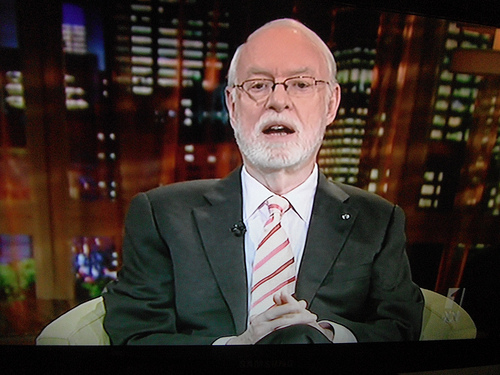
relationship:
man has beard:
[103, 17, 424, 345] [229, 115, 325, 169]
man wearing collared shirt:
[103, 17, 424, 345] [239, 163, 318, 330]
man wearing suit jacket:
[103, 17, 424, 345] [100, 163, 424, 344]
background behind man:
[1, 1, 497, 343] [103, 17, 424, 345]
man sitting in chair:
[103, 17, 424, 345] [36, 274, 477, 346]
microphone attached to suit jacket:
[230, 217, 248, 237] [100, 163, 424, 344]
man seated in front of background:
[103, 17, 424, 345] [1, 1, 497, 343]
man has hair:
[103, 17, 424, 345] [227, 16, 337, 89]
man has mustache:
[103, 17, 424, 345] [251, 112, 300, 135]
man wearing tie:
[103, 17, 424, 345] [249, 195, 295, 328]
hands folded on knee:
[238, 287, 326, 343] [255, 322, 332, 343]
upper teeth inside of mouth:
[269, 124, 283, 131] [260, 120, 296, 141]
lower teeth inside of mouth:
[269, 131, 288, 136] [260, 120, 296, 141]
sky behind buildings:
[2, 1, 105, 71] [1, 1, 499, 343]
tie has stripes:
[249, 195, 295, 328] [250, 203, 297, 319]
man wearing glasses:
[103, 17, 424, 345] [232, 75, 329, 97]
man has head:
[103, 17, 424, 345] [224, 18, 342, 172]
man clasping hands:
[103, 17, 424, 345] [238, 287, 326, 343]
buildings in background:
[1, 1, 499, 343] [1, 1, 497, 343]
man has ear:
[103, 17, 424, 345] [325, 84, 341, 129]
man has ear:
[103, 17, 424, 345] [222, 85, 237, 126]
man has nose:
[103, 17, 424, 345] [263, 80, 292, 113]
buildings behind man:
[1, 1, 499, 343] [103, 17, 424, 345]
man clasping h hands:
[103, 17, 424, 345] [238, 287, 326, 343]